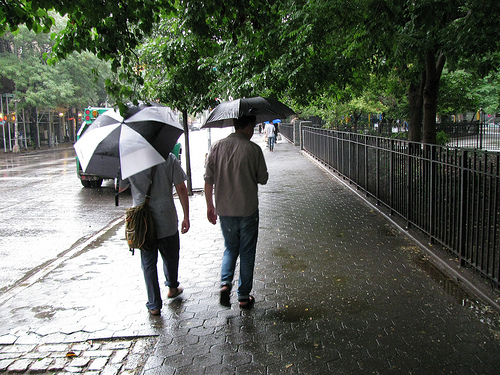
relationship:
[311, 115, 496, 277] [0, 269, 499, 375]
black fence by ground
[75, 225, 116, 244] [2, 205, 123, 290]
water by curb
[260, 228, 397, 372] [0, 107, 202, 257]
brick sidewalk by road